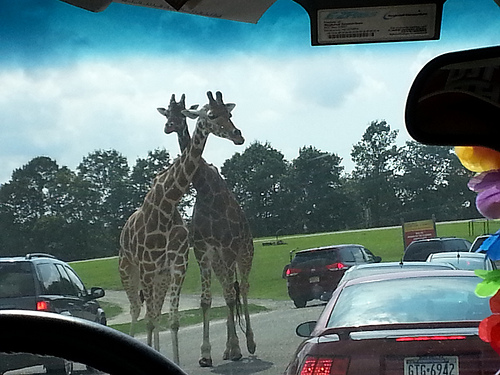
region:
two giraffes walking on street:
[109, 73, 288, 374]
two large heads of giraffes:
[152, 81, 248, 150]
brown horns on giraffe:
[200, 85, 227, 110]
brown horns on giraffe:
[162, 86, 189, 108]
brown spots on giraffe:
[121, 208, 172, 257]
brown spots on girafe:
[198, 203, 234, 243]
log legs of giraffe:
[175, 261, 270, 373]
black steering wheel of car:
[0, 306, 120, 342]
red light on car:
[300, 355, 332, 374]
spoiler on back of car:
[304, 313, 474, 347]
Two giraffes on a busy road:
[100, 85, 265, 373]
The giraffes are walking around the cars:
[15, 16, 495, 372]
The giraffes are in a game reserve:
[6, 21, 483, 352]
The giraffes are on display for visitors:
[15, 31, 486, 372]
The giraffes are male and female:
[30, 20, 465, 371]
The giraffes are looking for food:
[30, 22, 475, 372]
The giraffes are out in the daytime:
[31, 18, 476, 373]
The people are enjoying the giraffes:
[2, 3, 489, 363]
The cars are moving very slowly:
[18, 16, 486, 371]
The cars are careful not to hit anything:
[32, 30, 477, 361]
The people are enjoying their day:
[27, 27, 474, 362]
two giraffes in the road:
[110, 91, 275, 373]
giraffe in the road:
[157, 89, 281, 366]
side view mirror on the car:
[93, 281, 104, 300]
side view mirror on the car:
[373, 253, 385, 263]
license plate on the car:
[407, 357, 457, 373]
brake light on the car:
[281, 267, 299, 277]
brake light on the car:
[328, 264, 345, 272]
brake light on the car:
[300, 353, 342, 374]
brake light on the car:
[35, 302, 51, 310]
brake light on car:
[394, 337, 468, 342]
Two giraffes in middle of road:
[110, 90, 279, 358]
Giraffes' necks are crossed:
[154, 110, 222, 185]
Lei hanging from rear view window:
[442, 133, 499, 349]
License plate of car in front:
[401, 345, 462, 374]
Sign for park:
[388, 205, 440, 241]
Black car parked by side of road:
[281, 240, 381, 303]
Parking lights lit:
[285, 263, 348, 280]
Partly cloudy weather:
[12, 65, 406, 152]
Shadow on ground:
[214, 353, 269, 373]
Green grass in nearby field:
[254, 235, 284, 303]